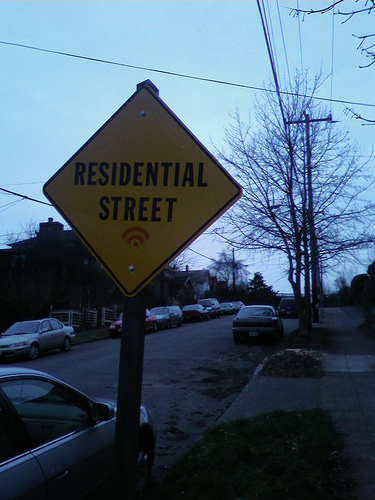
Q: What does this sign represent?
A: People's homes on this street.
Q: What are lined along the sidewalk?
A: Cars.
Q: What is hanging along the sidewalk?
A: Telephone wires.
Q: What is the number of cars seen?
A: 10.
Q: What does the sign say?
A: Residential Street.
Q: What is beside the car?
A: Street sign.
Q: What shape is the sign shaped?
A: Diamond.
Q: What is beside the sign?
A: Silver car.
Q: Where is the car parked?
A: On the street.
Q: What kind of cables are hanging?
A: Power lines.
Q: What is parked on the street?
A: Cars.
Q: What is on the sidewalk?
A: Grass.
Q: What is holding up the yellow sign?
A: Metal pole.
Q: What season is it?
A: Winter.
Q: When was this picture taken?
A: During the day.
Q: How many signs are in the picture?
A: One.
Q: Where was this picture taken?
A: Side of the road.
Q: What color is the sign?
A: Yellow.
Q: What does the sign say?
A: Residential Street.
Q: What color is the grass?
A: Green.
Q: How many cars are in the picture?
A: Ten.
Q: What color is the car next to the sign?
A: Grey.